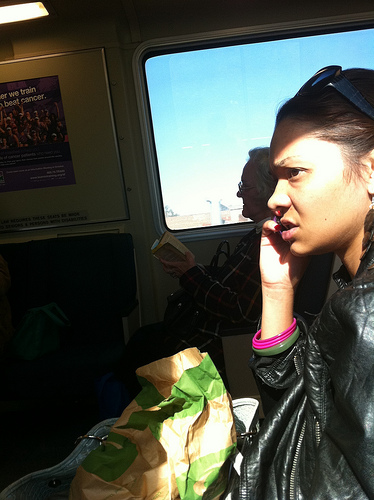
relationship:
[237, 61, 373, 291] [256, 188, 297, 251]
woman on phone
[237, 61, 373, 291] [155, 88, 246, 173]
woman face sun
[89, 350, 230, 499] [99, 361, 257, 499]
bag on lap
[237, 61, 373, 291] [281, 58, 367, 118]
woman with glasses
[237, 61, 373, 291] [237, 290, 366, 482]
woman wearing black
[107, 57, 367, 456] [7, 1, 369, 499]
people on train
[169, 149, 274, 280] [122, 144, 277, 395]
woman reading man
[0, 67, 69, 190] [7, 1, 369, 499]
advertisement on train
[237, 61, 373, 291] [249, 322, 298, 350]
woman with pink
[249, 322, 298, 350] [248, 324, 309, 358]
pink and green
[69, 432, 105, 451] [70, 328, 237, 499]
clasp for bag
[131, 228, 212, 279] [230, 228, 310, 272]
book behind hand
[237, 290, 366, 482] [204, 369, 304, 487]
black jacket zippers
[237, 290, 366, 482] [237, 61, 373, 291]
black glasses head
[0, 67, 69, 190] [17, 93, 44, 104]
sign for cancer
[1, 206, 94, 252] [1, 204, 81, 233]
row of black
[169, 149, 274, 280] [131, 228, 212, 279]
woman reading book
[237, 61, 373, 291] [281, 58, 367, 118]
lady has glasses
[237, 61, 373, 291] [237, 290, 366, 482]
lady wearing coat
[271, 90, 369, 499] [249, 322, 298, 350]
lady has bracelets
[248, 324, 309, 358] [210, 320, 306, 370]
green and purple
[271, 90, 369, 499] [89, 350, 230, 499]
lady holding parcel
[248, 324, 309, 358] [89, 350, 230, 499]
green and brown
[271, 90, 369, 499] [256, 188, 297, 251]
lady on phone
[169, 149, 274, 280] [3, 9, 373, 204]
man in background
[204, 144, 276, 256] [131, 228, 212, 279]
man reading book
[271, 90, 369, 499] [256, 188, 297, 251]
girl on phone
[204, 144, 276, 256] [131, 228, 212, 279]
lady reading book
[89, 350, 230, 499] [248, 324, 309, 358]
brown and green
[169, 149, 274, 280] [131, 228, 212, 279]
lady reading book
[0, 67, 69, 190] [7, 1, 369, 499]
advertising on train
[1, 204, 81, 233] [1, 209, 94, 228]
white black lettering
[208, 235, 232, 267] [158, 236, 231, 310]
leather straps purse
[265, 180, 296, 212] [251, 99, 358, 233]
nose on face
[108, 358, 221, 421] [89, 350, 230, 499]
green paper sack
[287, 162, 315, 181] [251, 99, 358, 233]
eye on face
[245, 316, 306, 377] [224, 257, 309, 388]
bracelets on arm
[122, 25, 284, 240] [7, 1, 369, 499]
window on train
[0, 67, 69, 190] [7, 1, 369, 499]
sign on train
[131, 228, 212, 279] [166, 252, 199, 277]
book in hands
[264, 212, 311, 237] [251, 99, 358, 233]
mouth on face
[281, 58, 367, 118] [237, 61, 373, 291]
glasses on head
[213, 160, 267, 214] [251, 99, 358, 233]
profile of face